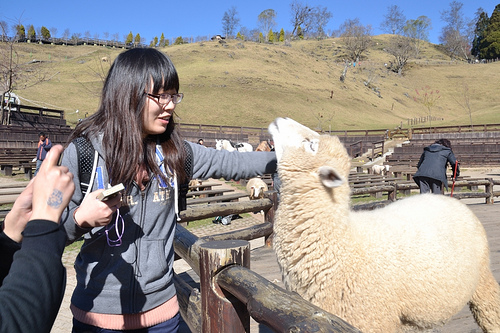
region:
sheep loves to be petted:
[266, 92, 495, 331]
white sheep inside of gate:
[256, 110, 498, 332]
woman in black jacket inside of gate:
[417, 121, 462, 197]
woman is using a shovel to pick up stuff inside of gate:
[413, 117, 460, 212]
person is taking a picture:
[2, 139, 77, 326]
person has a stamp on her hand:
[28, 137, 75, 226]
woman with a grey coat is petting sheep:
[63, 30, 394, 320]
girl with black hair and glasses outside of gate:
[86, 47, 189, 185]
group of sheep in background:
[218, 138, 270, 199]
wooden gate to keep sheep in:
[177, 216, 364, 328]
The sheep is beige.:
[254, 118, 494, 318]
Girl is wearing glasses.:
[145, 84, 190, 116]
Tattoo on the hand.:
[37, 181, 74, 218]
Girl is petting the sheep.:
[252, 117, 357, 231]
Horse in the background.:
[202, 136, 263, 167]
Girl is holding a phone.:
[86, 179, 139, 213]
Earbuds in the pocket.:
[93, 216, 147, 259]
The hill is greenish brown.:
[193, 66, 335, 127]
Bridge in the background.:
[18, 20, 173, 53]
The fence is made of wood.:
[173, 233, 295, 329]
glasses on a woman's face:
[150, 85, 186, 105]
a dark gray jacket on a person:
[410, 140, 452, 177]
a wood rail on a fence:
[180, 190, 270, 217]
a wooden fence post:
[190, 235, 250, 330]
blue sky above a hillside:
[8, 1, 496, 46]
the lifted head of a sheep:
[264, 114, 350, 197]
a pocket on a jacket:
[137, 236, 182, 285]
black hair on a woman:
[65, 45, 185, 207]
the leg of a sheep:
[469, 270, 498, 328]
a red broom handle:
[450, 150, 460, 198]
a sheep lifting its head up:
[256, 110, 499, 329]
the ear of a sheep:
[314, 163, 343, 192]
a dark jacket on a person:
[413, 140, 456, 187]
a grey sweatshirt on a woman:
[62, 137, 279, 313]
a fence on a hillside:
[404, 109, 445, 128]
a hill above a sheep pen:
[0, 29, 498, 131]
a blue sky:
[0, 0, 497, 40]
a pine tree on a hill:
[474, 10, 497, 63]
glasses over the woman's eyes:
[140, 90, 189, 107]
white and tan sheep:
[259, 116, 499, 332]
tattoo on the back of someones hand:
[43, 189, 68, 209]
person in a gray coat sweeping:
[409, 134, 467, 193]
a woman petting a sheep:
[43, 43, 353, 330]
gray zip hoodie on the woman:
[60, 133, 277, 313]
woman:
[41, 46, 278, 332]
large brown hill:
[6, 6, 494, 119]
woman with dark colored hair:
[51, 41, 273, 330]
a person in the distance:
[26, 129, 53, 171]